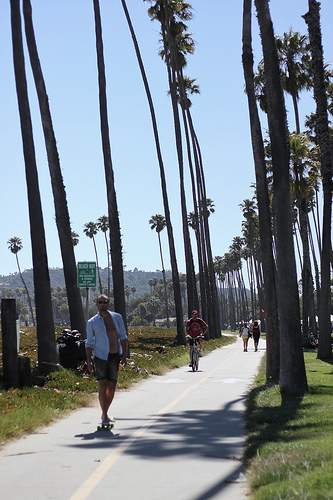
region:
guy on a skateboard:
[76, 292, 129, 441]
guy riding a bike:
[179, 307, 213, 374]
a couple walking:
[239, 317, 261, 356]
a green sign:
[72, 257, 100, 315]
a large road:
[1, 308, 269, 498]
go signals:
[144, 374, 249, 390]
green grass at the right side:
[244, 322, 330, 498]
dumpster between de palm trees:
[54, 322, 88, 374]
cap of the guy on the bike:
[191, 307, 200, 316]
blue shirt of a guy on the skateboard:
[83, 307, 130, 365]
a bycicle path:
[25, 311, 264, 497]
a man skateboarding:
[81, 294, 134, 449]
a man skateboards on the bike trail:
[81, 292, 135, 444]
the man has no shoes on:
[78, 294, 129, 450]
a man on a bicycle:
[186, 309, 207, 376]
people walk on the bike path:
[237, 311, 269, 353]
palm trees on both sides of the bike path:
[29, 212, 330, 393]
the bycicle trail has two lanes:
[24, 321, 262, 498]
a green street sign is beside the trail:
[78, 258, 104, 359]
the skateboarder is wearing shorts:
[81, 294, 130, 431]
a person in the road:
[84, 287, 145, 427]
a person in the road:
[183, 303, 207, 371]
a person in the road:
[236, 317, 249, 348]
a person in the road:
[248, 315, 261, 346]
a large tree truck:
[277, 238, 304, 397]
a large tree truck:
[260, 255, 284, 378]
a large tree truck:
[27, 201, 61, 367]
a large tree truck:
[64, 248, 89, 335]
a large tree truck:
[111, 233, 128, 320]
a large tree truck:
[318, 270, 329, 358]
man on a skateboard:
[83, 293, 122, 430]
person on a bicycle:
[178, 305, 213, 373]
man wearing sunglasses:
[84, 288, 128, 447]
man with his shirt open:
[89, 291, 129, 452]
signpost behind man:
[73, 252, 101, 294]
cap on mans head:
[189, 307, 200, 322]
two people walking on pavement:
[240, 318, 264, 360]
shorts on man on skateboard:
[84, 345, 133, 391]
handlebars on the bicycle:
[182, 329, 207, 346]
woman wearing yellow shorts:
[233, 317, 252, 356]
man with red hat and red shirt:
[180, 301, 218, 383]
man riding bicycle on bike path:
[179, 309, 215, 385]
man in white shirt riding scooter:
[84, 293, 127, 451]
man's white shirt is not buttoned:
[81, 293, 136, 361]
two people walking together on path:
[237, 314, 266, 367]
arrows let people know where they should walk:
[156, 368, 249, 407]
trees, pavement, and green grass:
[232, 294, 321, 423]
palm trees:
[125, 288, 148, 311]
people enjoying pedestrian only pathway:
[59, 292, 276, 477]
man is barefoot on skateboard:
[85, 405, 138, 452]